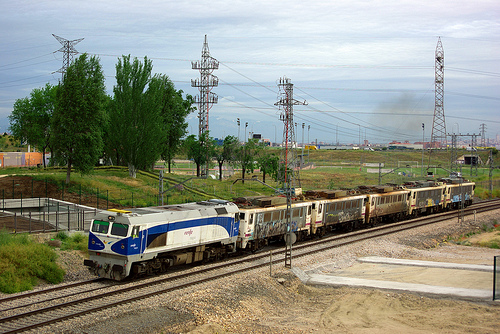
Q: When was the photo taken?
A: Daytime.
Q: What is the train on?
A: Tracks.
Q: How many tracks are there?
A: Two.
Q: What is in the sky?
A: Clouds.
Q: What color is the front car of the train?
A: White and blue.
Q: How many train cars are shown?
A: Six.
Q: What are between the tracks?
A: Gravel.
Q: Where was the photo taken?
A: At a railway area in a rural part of town.